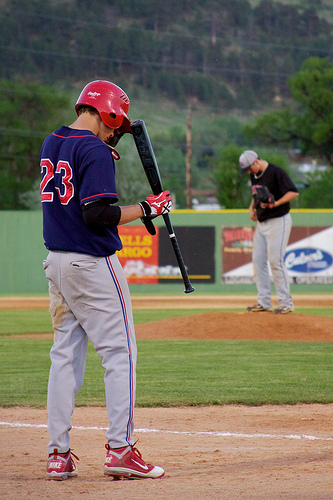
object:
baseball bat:
[128, 121, 194, 293]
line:
[0, 421, 332, 440]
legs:
[81, 285, 136, 440]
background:
[0, 0, 333, 499]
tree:
[241, 54, 333, 170]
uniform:
[39, 125, 138, 456]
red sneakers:
[103, 437, 164, 480]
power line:
[0, 8, 333, 55]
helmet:
[75, 78, 131, 147]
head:
[72, 79, 131, 143]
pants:
[42, 251, 138, 451]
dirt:
[134, 310, 333, 340]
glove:
[137, 189, 173, 236]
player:
[39, 79, 172, 478]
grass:
[0, 306, 333, 408]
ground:
[0, 291, 333, 498]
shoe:
[44, 449, 79, 477]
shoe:
[273, 306, 295, 315]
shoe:
[246, 302, 271, 313]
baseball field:
[0, 289, 332, 499]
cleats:
[68, 446, 80, 461]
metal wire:
[0, 47, 293, 79]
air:
[0, 0, 55, 68]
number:
[38, 157, 56, 204]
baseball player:
[235, 149, 299, 315]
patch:
[0, 336, 333, 407]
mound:
[132, 308, 333, 340]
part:
[116, 291, 234, 366]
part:
[186, 179, 228, 215]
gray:
[114, 368, 125, 402]